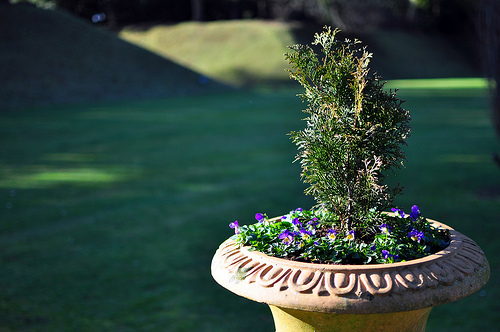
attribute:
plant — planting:
[281, 22, 415, 250]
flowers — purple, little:
[222, 194, 457, 265]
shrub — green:
[287, 31, 406, 263]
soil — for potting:
[273, 211, 435, 296]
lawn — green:
[2, 76, 493, 329]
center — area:
[248, 210, 435, 260]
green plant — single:
[283, 23, 413, 234]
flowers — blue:
[231, 179, 451, 261]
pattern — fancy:
[221, 235, 481, 292]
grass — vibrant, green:
[101, 110, 251, 190]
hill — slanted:
[35, 5, 343, 113]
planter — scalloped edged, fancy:
[188, 200, 490, 310]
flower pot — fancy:
[209, 207, 491, 330]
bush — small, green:
[282, 25, 413, 241]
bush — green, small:
[284, 28, 409, 224]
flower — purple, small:
[278, 229, 295, 244]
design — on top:
[229, 263, 476, 297]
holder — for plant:
[207, 259, 492, 330]